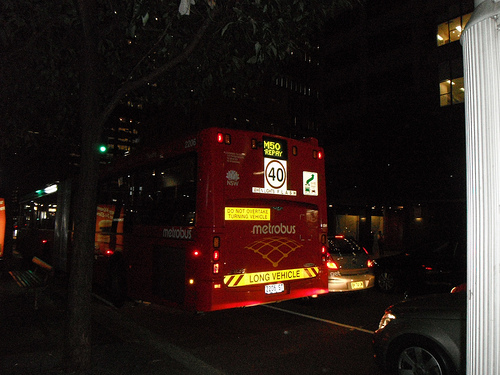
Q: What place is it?
A: It is a street.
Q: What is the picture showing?
A: It is showing a street.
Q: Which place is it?
A: It is a street.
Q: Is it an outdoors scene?
A: Yes, it is outdoors.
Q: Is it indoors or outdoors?
A: It is outdoors.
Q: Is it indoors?
A: No, it is outdoors.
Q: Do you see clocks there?
A: No, there are no clocks.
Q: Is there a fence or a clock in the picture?
A: No, there are no clocks or fences.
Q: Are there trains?
A: No, there are no trains.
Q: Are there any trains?
A: No, there are no trains.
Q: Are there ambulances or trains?
A: No, there are no trains or ambulances.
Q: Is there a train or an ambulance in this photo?
A: No, there are no trains or ambulances.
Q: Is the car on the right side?
A: Yes, the car is on the right of the image.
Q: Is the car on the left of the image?
A: No, the car is on the right of the image.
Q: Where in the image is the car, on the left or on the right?
A: The car is on the right of the image.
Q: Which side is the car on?
A: The car is on the right of the image.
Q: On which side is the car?
A: The car is on the right of the image.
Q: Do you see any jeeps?
A: No, there are no jeeps.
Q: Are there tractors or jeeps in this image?
A: No, there are no jeeps or tractors.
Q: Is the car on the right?
A: Yes, the car is on the right of the image.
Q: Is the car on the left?
A: No, the car is on the right of the image.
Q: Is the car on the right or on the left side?
A: The car is on the right of the image.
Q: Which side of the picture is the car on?
A: The car is on the right of the image.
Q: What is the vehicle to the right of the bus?
A: The vehicle is a car.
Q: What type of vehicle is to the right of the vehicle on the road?
A: The vehicle is a car.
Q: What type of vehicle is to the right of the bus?
A: The vehicle is a car.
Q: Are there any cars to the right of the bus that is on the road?
A: Yes, there is a car to the right of the bus.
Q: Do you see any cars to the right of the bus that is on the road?
A: Yes, there is a car to the right of the bus.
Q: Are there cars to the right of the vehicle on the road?
A: Yes, there is a car to the right of the bus.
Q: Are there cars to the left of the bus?
A: No, the car is to the right of the bus.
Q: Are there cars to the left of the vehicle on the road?
A: No, the car is to the right of the bus.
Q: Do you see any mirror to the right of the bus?
A: No, there is a car to the right of the bus.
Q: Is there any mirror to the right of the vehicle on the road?
A: No, there is a car to the right of the bus.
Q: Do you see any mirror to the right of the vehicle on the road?
A: No, there is a car to the right of the bus.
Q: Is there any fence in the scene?
A: No, there are no fences.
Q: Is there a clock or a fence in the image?
A: No, there are no fences or clocks.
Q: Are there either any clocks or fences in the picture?
A: No, there are no fences or clocks.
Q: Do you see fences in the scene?
A: No, there are no fences.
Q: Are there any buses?
A: Yes, there is a bus.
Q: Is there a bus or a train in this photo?
A: Yes, there is a bus.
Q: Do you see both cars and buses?
A: Yes, there are both a bus and a car.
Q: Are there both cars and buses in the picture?
A: Yes, there are both a bus and a car.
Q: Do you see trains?
A: No, there are no trains.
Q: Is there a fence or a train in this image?
A: No, there are no trains or fences.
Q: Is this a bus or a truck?
A: This is a bus.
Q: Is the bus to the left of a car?
A: Yes, the bus is to the left of a car.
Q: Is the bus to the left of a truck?
A: No, the bus is to the left of a car.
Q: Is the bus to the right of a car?
A: No, the bus is to the left of a car.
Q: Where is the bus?
A: The bus is on the road.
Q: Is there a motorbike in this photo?
A: No, there are no motorcycles.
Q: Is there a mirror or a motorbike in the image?
A: No, there are no motorcycles or mirrors.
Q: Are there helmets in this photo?
A: No, there are no helmets.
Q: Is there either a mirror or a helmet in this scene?
A: No, there are no helmets or mirrors.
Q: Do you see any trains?
A: No, there are no trains.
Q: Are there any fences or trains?
A: No, there are no trains or fences.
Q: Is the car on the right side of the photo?
A: Yes, the car is on the right of the image.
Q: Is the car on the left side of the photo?
A: No, the car is on the right of the image.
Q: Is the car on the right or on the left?
A: The car is on the right of the image.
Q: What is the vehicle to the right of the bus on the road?
A: The vehicle is a car.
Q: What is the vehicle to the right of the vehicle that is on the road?
A: The vehicle is a car.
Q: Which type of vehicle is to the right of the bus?
A: The vehicle is a car.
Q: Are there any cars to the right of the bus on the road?
A: Yes, there is a car to the right of the bus.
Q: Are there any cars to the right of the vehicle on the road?
A: Yes, there is a car to the right of the bus.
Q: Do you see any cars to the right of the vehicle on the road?
A: Yes, there is a car to the right of the bus.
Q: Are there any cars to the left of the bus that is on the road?
A: No, the car is to the right of the bus.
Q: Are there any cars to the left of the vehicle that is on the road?
A: No, the car is to the right of the bus.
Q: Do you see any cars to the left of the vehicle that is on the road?
A: No, the car is to the right of the bus.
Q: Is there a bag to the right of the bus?
A: No, there is a car to the right of the bus.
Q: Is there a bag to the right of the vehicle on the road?
A: No, there is a car to the right of the bus.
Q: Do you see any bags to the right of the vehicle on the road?
A: No, there is a car to the right of the bus.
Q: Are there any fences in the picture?
A: No, there are no fences.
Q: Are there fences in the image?
A: No, there are no fences.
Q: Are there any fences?
A: No, there are no fences.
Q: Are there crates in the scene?
A: No, there are no crates.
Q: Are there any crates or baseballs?
A: No, there are no crates or baseballs.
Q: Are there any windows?
A: Yes, there is a window.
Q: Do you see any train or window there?
A: Yes, there is a window.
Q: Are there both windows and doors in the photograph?
A: No, there is a window but no doors.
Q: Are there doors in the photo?
A: No, there are no doors.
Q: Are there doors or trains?
A: No, there are no doors or trains.